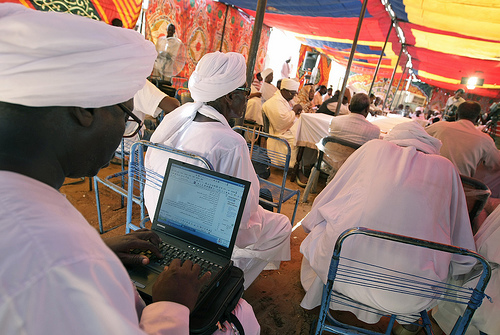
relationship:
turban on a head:
[188, 44, 250, 102] [184, 48, 256, 137]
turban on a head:
[0, 5, 159, 110] [3, 5, 163, 193]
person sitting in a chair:
[171, 50, 301, 280] [129, 135, 227, 238]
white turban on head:
[382, 115, 440, 156] [382, 109, 453, 168]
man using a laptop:
[1, 1, 264, 334] [110, 152, 252, 309]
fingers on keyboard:
[129, 222, 213, 280] [165, 245, 184, 258]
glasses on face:
[115, 96, 143, 139] [90, 96, 143, 179]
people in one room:
[263, 63, 489, 270] [1, 1, 499, 326]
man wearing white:
[1, 1, 264, 334] [11, 53, 53, 272]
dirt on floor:
[267, 282, 295, 315] [86, 164, 311, 328]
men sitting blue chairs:
[120, 54, 470, 292] [236, 117, 303, 250]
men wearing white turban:
[120, 54, 470, 292] [382, 115, 440, 156]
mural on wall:
[143, 2, 270, 72] [9, 0, 345, 88]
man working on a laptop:
[1, 1, 264, 334] [110, 152, 252, 309]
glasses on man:
[115, 96, 143, 139] [1, 1, 264, 334]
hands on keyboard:
[129, 222, 213, 280] [165, 245, 184, 258]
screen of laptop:
[156, 157, 246, 246] [110, 152, 252, 309]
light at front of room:
[460, 72, 483, 96] [1, 1, 499, 326]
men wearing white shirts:
[120, 54, 470, 292] [329, 114, 375, 141]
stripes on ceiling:
[229, 3, 497, 92] [381, 10, 472, 75]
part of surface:
[323, 37, 341, 48] [223, 4, 402, 83]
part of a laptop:
[199, 252, 215, 266] [110, 152, 252, 309]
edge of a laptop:
[233, 182, 249, 200] [110, 152, 252, 309]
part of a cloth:
[174, 119, 186, 127] [151, 103, 199, 142]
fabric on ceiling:
[369, 31, 385, 47] [381, 10, 472, 75]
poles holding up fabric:
[345, 0, 407, 105] [369, 31, 385, 47]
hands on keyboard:
[98, 218, 210, 319] [165, 245, 184, 258]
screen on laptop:
[156, 157, 246, 246] [110, 152, 252, 309]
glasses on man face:
[115, 96, 143, 139] [90, 96, 143, 179]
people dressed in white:
[263, 63, 489, 270] [11, 53, 53, 272]